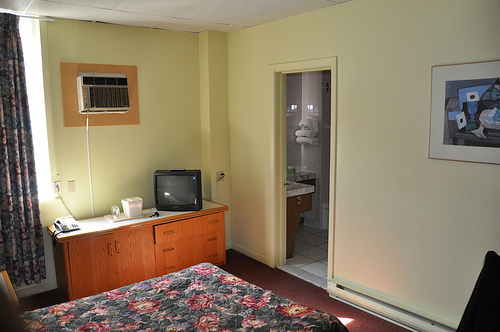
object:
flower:
[183, 288, 215, 311]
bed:
[2, 260, 356, 329]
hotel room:
[0, 2, 498, 327]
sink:
[284, 164, 308, 179]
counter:
[288, 165, 320, 251]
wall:
[25, 19, 230, 209]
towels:
[296, 136, 322, 146]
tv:
[153, 169, 201, 213]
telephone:
[47, 213, 82, 247]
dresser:
[48, 196, 227, 299]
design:
[1, 263, 349, 332]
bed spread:
[11, 261, 349, 329]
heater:
[329, 275, 457, 332]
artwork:
[428, 60, 498, 169]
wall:
[227, 1, 498, 330]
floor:
[288, 216, 328, 275]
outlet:
[51, 181, 63, 197]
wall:
[19, 9, 232, 249]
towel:
[293, 128, 319, 138]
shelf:
[295, 133, 312, 138]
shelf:
[296, 142, 314, 147]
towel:
[298, 114, 322, 129]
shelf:
[299, 123, 315, 127]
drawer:
[157, 244, 227, 277]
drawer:
[153, 231, 225, 260]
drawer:
[150, 212, 226, 243]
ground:
[223, 274, 349, 306]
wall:
[341, 17, 492, 322]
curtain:
[0, 12, 48, 287]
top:
[45, 194, 226, 239]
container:
[118, 194, 145, 220]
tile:
[293, 243, 331, 265]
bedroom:
[0, 0, 498, 329]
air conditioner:
[76, 71, 139, 119]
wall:
[6, 13, 237, 302]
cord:
[53, 197, 80, 220]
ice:
[129, 200, 142, 205]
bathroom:
[273, 70, 329, 291]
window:
[1, 14, 58, 292]